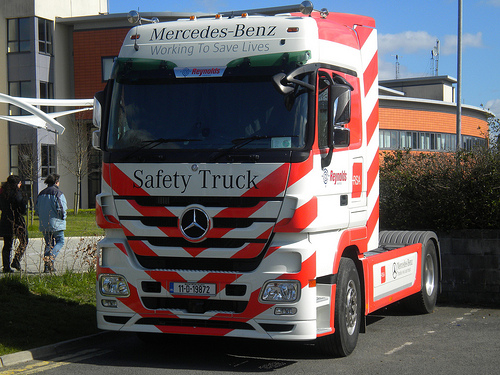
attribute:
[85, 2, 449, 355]
truck cab — red, white, mercedes-benz, orange, large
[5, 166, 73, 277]
girls — walking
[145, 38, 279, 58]
lettering — working to save live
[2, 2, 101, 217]
building — brick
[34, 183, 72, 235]
blue coat — warm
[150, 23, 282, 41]
logo — mercedes-benz